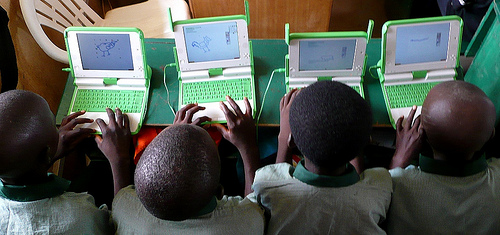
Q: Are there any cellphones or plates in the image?
A: No, there are no cellphones or plates.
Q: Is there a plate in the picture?
A: No, there are no plates.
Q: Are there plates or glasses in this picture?
A: No, there are no plates or glasses.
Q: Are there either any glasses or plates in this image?
A: No, there are no plates or glasses.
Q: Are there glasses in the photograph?
A: No, there are no glasses.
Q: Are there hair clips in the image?
A: No, there are no hair clips.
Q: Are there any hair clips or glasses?
A: No, there are no hair clips or glasses.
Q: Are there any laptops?
A: Yes, there is a laptop.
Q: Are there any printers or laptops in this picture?
A: Yes, there is a laptop.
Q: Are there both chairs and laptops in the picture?
A: Yes, there are both a laptop and a chair.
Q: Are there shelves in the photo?
A: No, there are no shelves.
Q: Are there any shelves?
A: No, there are no shelves.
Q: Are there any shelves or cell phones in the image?
A: No, there are no shelves or cell phones.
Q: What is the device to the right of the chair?
A: The device is a laptop.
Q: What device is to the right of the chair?
A: The device is a laptop.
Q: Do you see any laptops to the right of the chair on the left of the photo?
A: Yes, there is a laptop to the right of the chair.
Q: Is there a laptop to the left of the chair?
A: No, the laptop is to the right of the chair.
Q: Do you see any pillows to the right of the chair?
A: No, there is a laptop to the right of the chair.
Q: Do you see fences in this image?
A: No, there are no fences.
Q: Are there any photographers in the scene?
A: No, there are no photographers.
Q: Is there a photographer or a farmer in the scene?
A: No, there are no photographers or farmers.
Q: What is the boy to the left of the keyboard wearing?
A: The boy is wearing a shirt.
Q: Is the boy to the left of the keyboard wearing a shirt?
A: Yes, the boy is wearing a shirt.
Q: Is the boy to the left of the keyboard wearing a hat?
A: No, the boy is wearing a shirt.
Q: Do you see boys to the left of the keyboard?
A: Yes, there is a boy to the left of the keyboard.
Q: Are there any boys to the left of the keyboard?
A: Yes, there is a boy to the left of the keyboard.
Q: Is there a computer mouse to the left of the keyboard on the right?
A: No, there is a boy to the left of the keyboard.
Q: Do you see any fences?
A: No, there are no fences.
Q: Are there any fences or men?
A: No, there are no fences or men.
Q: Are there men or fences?
A: No, there are no fences or men.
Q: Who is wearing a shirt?
A: The boy is wearing a shirt.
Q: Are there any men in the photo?
A: No, there are no men.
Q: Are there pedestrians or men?
A: No, there are no men or pedestrians.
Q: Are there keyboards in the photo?
A: Yes, there is a keyboard.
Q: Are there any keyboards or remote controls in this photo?
A: Yes, there is a keyboard.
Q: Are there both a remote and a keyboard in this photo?
A: No, there is a keyboard but no remote controls.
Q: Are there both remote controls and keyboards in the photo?
A: No, there is a keyboard but no remote controls.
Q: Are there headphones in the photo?
A: No, there are no headphones.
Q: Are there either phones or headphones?
A: No, there are no headphones or phones.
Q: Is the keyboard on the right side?
A: Yes, the keyboard is on the right of the image.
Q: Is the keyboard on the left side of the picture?
A: No, the keyboard is on the right of the image.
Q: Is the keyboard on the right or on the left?
A: The keyboard is on the right of the image.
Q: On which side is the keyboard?
A: The keyboard is on the right of the image.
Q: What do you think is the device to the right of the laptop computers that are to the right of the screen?
A: The device is a keyboard.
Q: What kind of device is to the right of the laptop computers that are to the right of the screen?
A: The device is a keyboard.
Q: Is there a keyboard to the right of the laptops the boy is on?
A: Yes, there is a keyboard to the right of the laptops.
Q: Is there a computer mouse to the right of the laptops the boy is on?
A: No, there is a keyboard to the right of the laptops.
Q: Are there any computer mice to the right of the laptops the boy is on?
A: No, there is a keyboard to the right of the laptops.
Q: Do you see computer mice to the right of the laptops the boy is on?
A: No, there is a keyboard to the right of the laptops.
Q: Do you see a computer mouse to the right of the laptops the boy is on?
A: No, there is a keyboard to the right of the laptops.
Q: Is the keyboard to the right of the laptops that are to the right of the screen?
A: Yes, the keyboard is to the right of the laptops.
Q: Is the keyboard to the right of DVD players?
A: No, the keyboard is to the right of the laptops.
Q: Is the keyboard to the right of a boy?
A: Yes, the keyboard is to the right of a boy.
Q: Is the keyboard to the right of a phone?
A: No, the keyboard is to the right of a boy.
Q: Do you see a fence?
A: No, there are no fences.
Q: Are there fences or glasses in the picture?
A: No, there are no fences or glasses.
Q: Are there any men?
A: No, there are no men.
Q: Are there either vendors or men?
A: No, there are no men or vendors.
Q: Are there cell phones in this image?
A: No, there are no cell phones.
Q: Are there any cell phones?
A: No, there are no cell phones.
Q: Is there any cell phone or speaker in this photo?
A: No, there are no cell phones or speakers.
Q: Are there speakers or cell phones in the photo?
A: No, there are no cell phones or speakers.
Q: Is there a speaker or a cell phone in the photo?
A: No, there are no cell phones or speakers.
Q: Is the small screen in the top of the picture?
A: Yes, the screen is in the top of the image.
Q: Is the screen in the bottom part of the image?
A: No, the screen is in the top of the image.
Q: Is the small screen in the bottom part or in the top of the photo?
A: The screen is in the top of the image.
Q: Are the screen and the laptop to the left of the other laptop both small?
A: Yes, both the screen and the laptop computer are small.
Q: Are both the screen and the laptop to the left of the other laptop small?
A: Yes, both the screen and the laptop computer are small.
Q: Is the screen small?
A: Yes, the screen is small.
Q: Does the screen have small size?
A: Yes, the screen is small.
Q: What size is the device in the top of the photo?
A: The screen is small.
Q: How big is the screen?
A: The screen is small.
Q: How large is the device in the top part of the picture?
A: The screen is small.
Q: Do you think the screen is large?
A: No, the screen is small.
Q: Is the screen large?
A: No, the screen is small.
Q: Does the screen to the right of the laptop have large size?
A: No, the screen is small.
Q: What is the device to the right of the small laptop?
A: The device is a screen.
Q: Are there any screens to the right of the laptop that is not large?
A: Yes, there is a screen to the right of the laptop computer.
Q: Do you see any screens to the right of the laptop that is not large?
A: Yes, there is a screen to the right of the laptop computer.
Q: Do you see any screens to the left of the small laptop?
A: No, the screen is to the right of the laptop.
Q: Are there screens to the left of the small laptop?
A: No, the screen is to the right of the laptop.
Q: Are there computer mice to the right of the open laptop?
A: No, there is a screen to the right of the laptop.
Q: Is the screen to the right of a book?
A: No, the screen is to the right of the laptop computer.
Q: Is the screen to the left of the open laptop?
A: No, the screen is to the right of the laptop.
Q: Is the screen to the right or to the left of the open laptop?
A: The screen is to the right of the laptop.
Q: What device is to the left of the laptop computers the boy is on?
A: The device is a screen.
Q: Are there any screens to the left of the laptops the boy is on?
A: Yes, there is a screen to the left of the laptop computers.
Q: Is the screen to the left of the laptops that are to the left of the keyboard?
A: Yes, the screen is to the left of the laptops.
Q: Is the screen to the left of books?
A: No, the screen is to the left of the laptops.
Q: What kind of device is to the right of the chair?
A: The device is a screen.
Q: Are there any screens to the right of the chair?
A: Yes, there is a screen to the right of the chair.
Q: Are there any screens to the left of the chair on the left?
A: No, the screen is to the right of the chair.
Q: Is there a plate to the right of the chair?
A: No, there is a screen to the right of the chair.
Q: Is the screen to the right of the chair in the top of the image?
A: Yes, the screen is to the right of the chair.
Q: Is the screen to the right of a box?
A: No, the screen is to the right of the chair.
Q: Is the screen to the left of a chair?
A: No, the screen is to the right of a chair.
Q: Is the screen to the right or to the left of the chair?
A: The screen is to the right of the chair.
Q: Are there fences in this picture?
A: No, there are no fences.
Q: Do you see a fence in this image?
A: No, there are no fences.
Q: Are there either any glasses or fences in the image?
A: No, there are no fences or glasses.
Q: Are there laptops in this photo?
A: Yes, there are laptops.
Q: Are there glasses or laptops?
A: Yes, there are laptops.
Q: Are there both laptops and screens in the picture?
A: Yes, there are both laptops and a screen.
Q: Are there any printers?
A: No, there are no printers.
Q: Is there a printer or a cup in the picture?
A: No, there are no printers or cups.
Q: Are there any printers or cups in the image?
A: No, there are no printers or cups.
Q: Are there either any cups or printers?
A: No, there are no printers or cups.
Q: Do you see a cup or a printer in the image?
A: No, there are no printers or cups.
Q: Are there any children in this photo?
A: Yes, there are children.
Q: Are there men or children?
A: Yes, there are children.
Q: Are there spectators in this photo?
A: No, there are no spectators.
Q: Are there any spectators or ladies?
A: No, there are no spectators or ladies.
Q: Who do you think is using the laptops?
A: The children are using the laptops.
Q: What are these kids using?
A: The kids are using laptop computers.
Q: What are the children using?
A: The kids are using laptop computers.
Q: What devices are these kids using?
A: The kids are using laptops.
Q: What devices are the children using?
A: The kids are using laptops.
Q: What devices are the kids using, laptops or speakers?
A: The kids are using laptops.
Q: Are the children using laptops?
A: Yes, the children are using laptops.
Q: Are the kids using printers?
A: No, the kids are using laptops.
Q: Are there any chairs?
A: Yes, there is a chair.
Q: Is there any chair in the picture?
A: Yes, there is a chair.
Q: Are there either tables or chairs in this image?
A: Yes, there is a chair.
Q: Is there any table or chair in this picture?
A: Yes, there is a chair.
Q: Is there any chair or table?
A: Yes, there is a chair.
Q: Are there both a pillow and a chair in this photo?
A: No, there is a chair but no pillows.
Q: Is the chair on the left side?
A: Yes, the chair is on the left of the image.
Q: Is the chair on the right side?
A: No, the chair is on the left of the image.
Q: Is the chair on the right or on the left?
A: The chair is on the left of the image.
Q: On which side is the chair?
A: The chair is on the left of the image.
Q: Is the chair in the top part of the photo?
A: Yes, the chair is in the top of the image.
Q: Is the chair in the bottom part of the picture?
A: No, the chair is in the top of the image.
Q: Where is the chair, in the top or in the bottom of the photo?
A: The chair is in the top of the image.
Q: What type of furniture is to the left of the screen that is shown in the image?
A: The piece of furniture is a chair.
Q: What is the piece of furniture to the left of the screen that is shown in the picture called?
A: The piece of furniture is a chair.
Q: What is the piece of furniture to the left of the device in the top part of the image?
A: The piece of furniture is a chair.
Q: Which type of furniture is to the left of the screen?
A: The piece of furniture is a chair.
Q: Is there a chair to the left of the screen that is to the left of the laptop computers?
A: Yes, there is a chair to the left of the screen.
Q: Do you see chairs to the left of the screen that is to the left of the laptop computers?
A: Yes, there is a chair to the left of the screen.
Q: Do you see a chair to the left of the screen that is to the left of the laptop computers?
A: Yes, there is a chair to the left of the screen.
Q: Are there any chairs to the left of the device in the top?
A: Yes, there is a chair to the left of the screen.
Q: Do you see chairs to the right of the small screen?
A: No, the chair is to the left of the screen.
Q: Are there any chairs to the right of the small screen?
A: No, the chair is to the left of the screen.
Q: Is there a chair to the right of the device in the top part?
A: No, the chair is to the left of the screen.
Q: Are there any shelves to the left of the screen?
A: No, there is a chair to the left of the screen.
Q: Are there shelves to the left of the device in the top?
A: No, there is a chair to the left of the screen.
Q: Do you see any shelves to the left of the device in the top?
A: No, there is a chair to the left of the screen.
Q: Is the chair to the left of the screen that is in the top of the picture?
A: Yes, the chair is to the left of the screen.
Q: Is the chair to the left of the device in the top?
A: Yes, the chair is to the left of the screen.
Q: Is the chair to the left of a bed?
A: No, the chair is to the left of the screen.